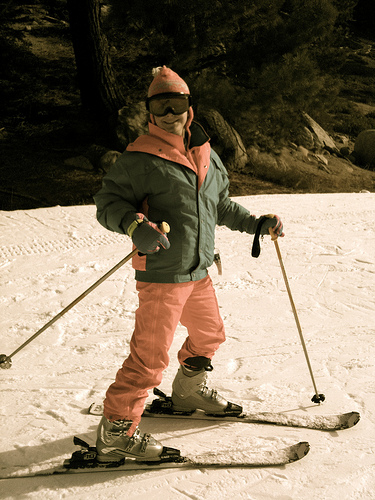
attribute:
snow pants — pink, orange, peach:
[102, 275, 225, 438]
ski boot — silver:
[92, 415, 180, 465]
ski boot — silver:
[171, 362, 242, 416]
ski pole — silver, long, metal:
[267, 223, 329, 405]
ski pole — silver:
[1, 221, 169, 368]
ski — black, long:
[89, 397, 360, 431]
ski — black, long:
[2, 435, 310, 478]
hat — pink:
[143, 64, 194, 147]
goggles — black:
[143, 91, 193, 117]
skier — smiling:
[95, 61, 289, 462]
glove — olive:
[121, 210, 171, 255]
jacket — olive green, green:
[93, 120, 255, 284]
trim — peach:
[128, 119, 212, 186]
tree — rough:
[62, 1, 126, 111]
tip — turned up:
[329, 410, 361, 431]